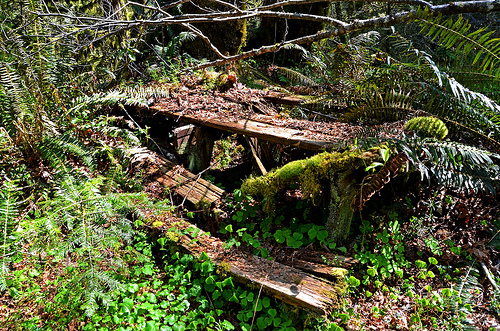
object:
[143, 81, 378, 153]
board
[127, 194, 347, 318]
board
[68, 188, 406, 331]
clovers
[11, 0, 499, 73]
branch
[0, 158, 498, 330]
ground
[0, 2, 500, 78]
trees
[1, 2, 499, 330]
jungle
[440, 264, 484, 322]
ivy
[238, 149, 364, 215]
moss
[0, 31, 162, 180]
fern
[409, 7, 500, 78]
leaf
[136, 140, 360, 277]
table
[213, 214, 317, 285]
shadow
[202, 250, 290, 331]
vine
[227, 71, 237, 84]
flower